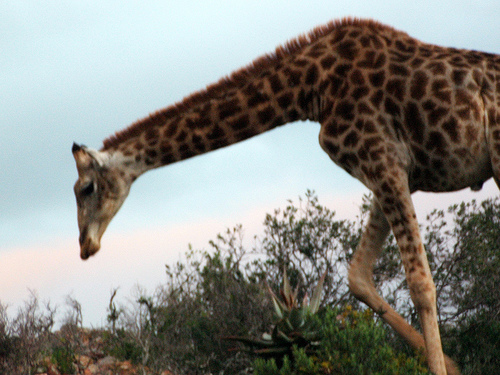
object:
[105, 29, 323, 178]
neck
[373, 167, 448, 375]
leg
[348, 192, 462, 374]
leg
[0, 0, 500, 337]
sky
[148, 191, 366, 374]
plant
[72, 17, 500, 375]
giraffe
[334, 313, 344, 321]
flowers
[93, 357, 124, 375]
rocks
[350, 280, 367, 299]
kneecap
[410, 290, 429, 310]
kneecap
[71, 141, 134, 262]
head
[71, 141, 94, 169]
horns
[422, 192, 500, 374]
trees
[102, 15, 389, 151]
mane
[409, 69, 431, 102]
spots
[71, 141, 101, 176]
ears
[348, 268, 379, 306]
knee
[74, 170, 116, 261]
face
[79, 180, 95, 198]
eye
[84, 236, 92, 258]
mouth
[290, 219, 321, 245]
leaves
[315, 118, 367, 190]
chest